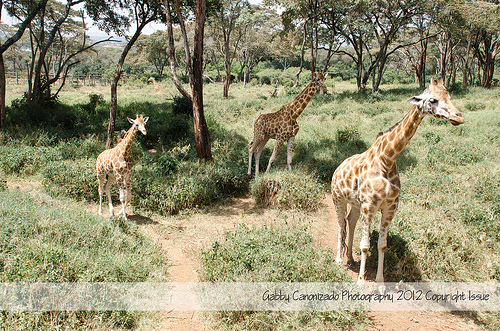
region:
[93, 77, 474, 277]
Giraffes standing near a grove of trees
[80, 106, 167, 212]
A young giraffe by a tree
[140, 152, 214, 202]
Tall grass underneath the tree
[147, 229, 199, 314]
A beaten dirt path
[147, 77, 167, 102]
A giraffe in the distance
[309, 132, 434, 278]
The giraffe is yellow and brown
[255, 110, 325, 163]
The giraffe has spots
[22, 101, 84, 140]
Shadow of a tree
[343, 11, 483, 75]
A grove of trees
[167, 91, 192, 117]
Small shrub growing by a tree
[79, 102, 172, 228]
one spotted giraffe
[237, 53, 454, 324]
two spotted giraffes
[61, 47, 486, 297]
three spotted giraffes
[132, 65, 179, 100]
one giraffe hiding in the background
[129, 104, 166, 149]
spotted giraffe's head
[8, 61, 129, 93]
type of fencing in the background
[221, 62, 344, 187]
spotted giraffe in the shade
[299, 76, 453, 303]
spotted giraffe in the sun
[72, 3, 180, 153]
skinny tree in the shade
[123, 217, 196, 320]
dirt path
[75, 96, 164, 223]
A baby giraffe standing in the wild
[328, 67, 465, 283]
An adult giraffe leading the way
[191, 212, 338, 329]
A patch of green grass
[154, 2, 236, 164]
A tree with green leaves on it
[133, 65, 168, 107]
A giraffe in the distance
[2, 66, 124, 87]
A wooden gate in the distance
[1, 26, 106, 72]
A shed behind the fence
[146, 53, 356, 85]
A long patch of bushes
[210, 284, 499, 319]
Name of the photography company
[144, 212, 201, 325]
Brown dirt on the ground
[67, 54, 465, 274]
three giraffes standing together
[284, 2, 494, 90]
short trees with thin branches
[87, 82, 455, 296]
two older giraffes with one young giraffe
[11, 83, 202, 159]
shadow cast on the bushes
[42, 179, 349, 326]
dirt pathway through the tall grass and brush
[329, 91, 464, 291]
giraffe with its head leaning forward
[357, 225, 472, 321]
shadow cast by a giraffe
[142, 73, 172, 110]
giraffe in the distance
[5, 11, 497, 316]
grassy area with trees in spots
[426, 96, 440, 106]
almond shaped eye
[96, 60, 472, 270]
Three giraffe's walking near each other.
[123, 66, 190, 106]
A giraffe in the distance.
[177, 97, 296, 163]
A giraffe near a tree.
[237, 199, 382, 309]
A giraffe walking near shrubs.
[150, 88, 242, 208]
A tree surrounded by shrubbery.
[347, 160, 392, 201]
The giraffe has orange markings on its body.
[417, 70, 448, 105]
Horns on the giraffe's head.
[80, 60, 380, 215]
A young giraffe near the left side of an adult giraffe.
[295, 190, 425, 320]
A giraffe walking on a dirt trail.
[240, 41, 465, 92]
Trees behind the giraffes.